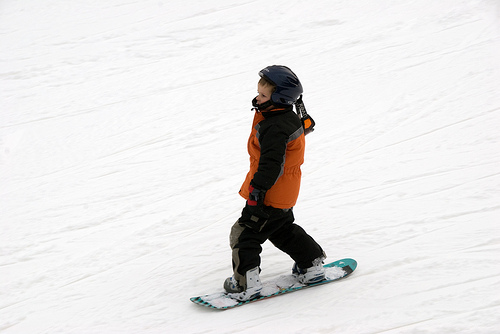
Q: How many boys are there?
A: One.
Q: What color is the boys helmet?
A: Black.